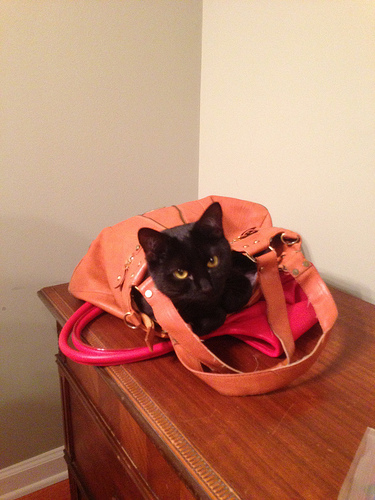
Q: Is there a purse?
A: Yes, there is a purse.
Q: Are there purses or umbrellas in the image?
A: Yes, there is a purse.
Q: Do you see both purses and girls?
A: No, there is a purse but no girls.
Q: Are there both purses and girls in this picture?
A: No, there is a purse but no girls.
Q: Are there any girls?
A: No, there are no girls.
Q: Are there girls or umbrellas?
A: No, there are no girls or umbrellas.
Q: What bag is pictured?
A: The bag is a purse.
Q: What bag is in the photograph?
A: The bag is a purse.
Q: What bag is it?
A: The bag is a purse.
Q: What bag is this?
A: This is a purse.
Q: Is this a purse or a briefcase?
A: This is a purse.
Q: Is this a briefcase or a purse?
A: This is a purse.